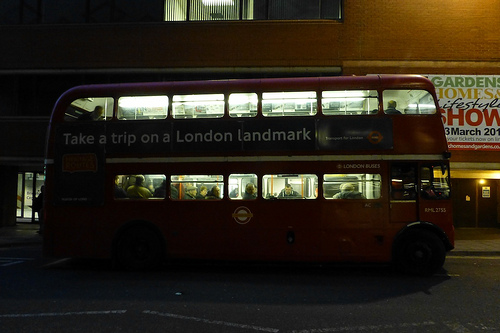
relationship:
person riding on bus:
[242, 181, 258, 200] [37, 72, 456, 279]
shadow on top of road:
[0, 263, 450, 303] [1, 240, 499, 333]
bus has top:
[37, 72, 456, 279] [43, 72, 448, 161]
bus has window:
[37, 72, 456, 279] [259, 87, 318, 117]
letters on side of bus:
[61, 129, 137, 148] [37, 72, 456, 279]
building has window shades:
[0, 1, 499, 226] [163, 0, 254, 23]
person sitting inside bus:
[242, 181, 258, 200] [37, 72, 456, 279]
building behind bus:
[0, 1, 499, 226] [37, 72, 456, 279]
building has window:
[0, 1, 499, 226] [252, 1, 341, 22]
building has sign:
[0, 1, 499, 226] [417, 74, 499, 153]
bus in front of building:
[37, 72, 456, 279] [0, 1, 499, 226]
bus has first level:
[37, 72, 456, 279] [42, 159, 456, 268]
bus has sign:
[37, 72, 456, 279] [58, 117, 391, 155]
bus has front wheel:
[37, 72, 456, 279] [393, 228, 448, 276]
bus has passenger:
[37, 72, 456, 279] [276, 184, 303, 199]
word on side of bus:
[174, 127, 235, 145] [37, 72, 456, 279]